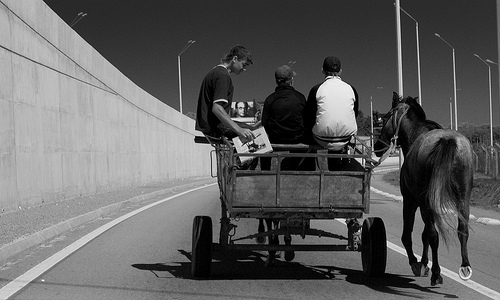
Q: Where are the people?
A: In the wagon.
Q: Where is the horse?
A: Next to the wagon.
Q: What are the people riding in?
A: A horse drawn vehicle.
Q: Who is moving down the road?
A: People in the cart.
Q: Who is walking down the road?
A: A horse.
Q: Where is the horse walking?
A: Beside the vehicle.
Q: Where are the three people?
A: In a vehicle.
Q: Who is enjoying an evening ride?
A: Three people in a cart.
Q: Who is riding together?
A: Three friends.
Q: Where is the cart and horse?
A: On the road.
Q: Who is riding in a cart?
A: Three people.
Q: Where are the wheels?
A: On the cart.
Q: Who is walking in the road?
A: A horse.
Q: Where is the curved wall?
A: Beside the road.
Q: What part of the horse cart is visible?
A: The back.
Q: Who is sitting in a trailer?
A: Three people.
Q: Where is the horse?
A: Walking in the road.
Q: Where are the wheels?
A: Under the trailer.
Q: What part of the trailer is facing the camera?
A: The back.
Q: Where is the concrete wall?
A: Next to the road.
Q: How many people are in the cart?
A: 3.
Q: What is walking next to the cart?
A: Another horse.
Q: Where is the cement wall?
A: On the far left of the photo.